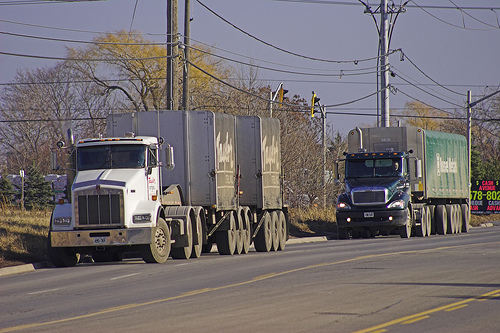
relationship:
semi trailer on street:
[334, 126, 471, 239] [7, 224, 499, 331]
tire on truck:
[415, 205, 435, 240] [341, 118, 471, 240]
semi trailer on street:
[48, 109, 288, 267] [7, 224, 499, 331]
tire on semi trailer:
[141, 215, 172, 265] [48, 109, 288, 267]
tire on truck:
[396, 206, 416, 236] [326, 79, 476, 280]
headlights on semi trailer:
[54, 218, 70, 225] [48, 109, 288, 267]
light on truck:
[53, 215, 71, 226] [335, 125, 471, 238]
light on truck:
[387, 197, 406, 207] [335, 125, 471, 238]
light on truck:
[338, 200, 345, 208] [335, 125, 471, 238]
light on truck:
[392, 198, 401, 208] [335, 125, 471, 238]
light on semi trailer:
[133, 215, 150, 222] [48, 109, 288, 267]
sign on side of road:
[470, 178, 499, 215] [0, 223, 498, 330]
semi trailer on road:
[48, 109, 288, 267] [0, 223, 498, 330]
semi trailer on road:
[334, 126, 471, 239] [0, 223, 498, 330]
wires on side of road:
[397, 49, 471, 94] [7, 260, 491, 332]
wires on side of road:
[201, 3, 377, 64] [7, 260, 491, 332]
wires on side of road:
[191, 75, 378, 115] [7, 260, 491, 332]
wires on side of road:
[5, 27, 159, 55] [7, 260, 491, 332]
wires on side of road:
[1, 76, 168, 87] [7, 260, 491, 332]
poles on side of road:
[367, 5, 405, 124] [7, 260, 491, 332]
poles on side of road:
[167, 0, 175, 107] [7, 260, 491, 332]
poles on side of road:
[182, 1, 191, 109] [7, 260, 491, 332]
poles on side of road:
[463, 89, 476, 229] [7, 260, 491, 332]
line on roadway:
[360, 297, 470, 331] [5, 271, 497, 331]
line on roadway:
[51, 295, 166, 323] [5, 271, 497, 331]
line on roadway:
[445, 304, 467, 314] [5, 271, 497, 331]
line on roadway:
[481, 294, 498, 301] [5, 271, 497, 331]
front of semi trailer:
[334, 150, 410, 226] [335, 124, 472, 237]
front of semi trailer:
[48, 135, 160, 251] [49, 106, 287, 263]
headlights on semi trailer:
[50, 211, 158, 231] [49, 106, 287, 263]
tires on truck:
[155, 202, 299, 266] [53, 112, 287, 264]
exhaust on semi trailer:
[65, 125, 75, 183] [49, 106, 287, 263]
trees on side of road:
[19, 37, 149, 123] [0, 223, 498, 330]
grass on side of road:
[2, 206, 484, 265] [0, 223, 498, 330]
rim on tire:
[152, 224, 168, 254] [147, 218, 174, 268]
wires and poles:
[185, 72, 496, 132] [163, 2, 195, 101]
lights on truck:
[387, 197, 404, 207] [331, 120, 474, 235]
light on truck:
[338, 203, 348, 209] [331, 120, 474, 235]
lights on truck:
[346, 148, 398, 158] [331, 120, 474, 235]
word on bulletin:
[480, 178, 494, 184] [469, 178, 499, 212]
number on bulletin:
[471, 189, 477, 201] [469, 178, 499, 212]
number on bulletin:
[475, 187, 483, 201] [469, 178, 499, 212]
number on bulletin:
[485, 190, 490, 198] [469, 178, 499, 212]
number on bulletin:
[490, 187, 496, 201] [469, 178, 499, 212]